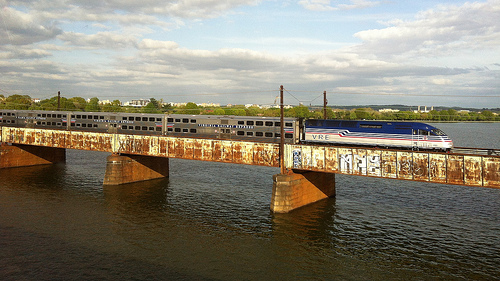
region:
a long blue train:
[303, 116, 455, 145]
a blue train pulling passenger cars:
[0, 106, 451, 148]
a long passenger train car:
[164, 115, 295, 142]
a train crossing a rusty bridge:
[0, 102, 495, 184]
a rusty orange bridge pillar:
[273, 160, 349, 209]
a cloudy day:
[364, 0, 497, 62]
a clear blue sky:
[219, 7, 374, 52]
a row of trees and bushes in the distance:
[3, 95, 496, 120]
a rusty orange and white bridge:
[0, 127, 492, 213]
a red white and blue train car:
[301, 120, 454, 143]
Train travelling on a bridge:
[4, 31, 456, 238]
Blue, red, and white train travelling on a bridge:
[17, 84, 464, 219]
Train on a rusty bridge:
[125, 95, 497, 229]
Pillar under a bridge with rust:
[263, 168, 342, 225]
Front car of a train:
[292, 117, 455, 154]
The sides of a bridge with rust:
[117, 136, 299, 167]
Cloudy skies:
[66, 20, 455, 80]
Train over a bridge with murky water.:
[2, 103, 499, 230]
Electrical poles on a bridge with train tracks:
[269, 80, 334, 230]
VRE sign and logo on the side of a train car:
[309, 124, 356, 150]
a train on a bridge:
[44, 29, 361, 254]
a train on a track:
[43, 51, 499, 272]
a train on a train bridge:
[76, 43, 481, 278]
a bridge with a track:
[136, 54, 458, 272]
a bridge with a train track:
[89, 62, 486, 261]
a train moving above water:
[93, 63, 399, 271]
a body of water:
[87, 184, 355, 276]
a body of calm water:
[85, 173, 365, 278]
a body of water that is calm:
[89, 177, 233, 265]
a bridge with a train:
[124, 72, 479, 252]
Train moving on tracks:
[0, 103, 499, 158]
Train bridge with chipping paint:
[0, 124, 499, 212]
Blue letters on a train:
[308, 131, 332, 139]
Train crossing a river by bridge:
[0, 106, 498, 215]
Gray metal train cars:
[1, 105, 298, 142]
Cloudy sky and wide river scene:
[2, 1, 497, 279]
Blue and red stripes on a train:
[280, 123, 450, 144]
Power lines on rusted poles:
[1, 84, 328, 177]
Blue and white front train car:
[299, 115, 453, 154]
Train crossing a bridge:
[0, 102, 498, 213]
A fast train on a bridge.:
[3, 103, 453, 150]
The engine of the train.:
[300, 111, 451, 146]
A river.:
[340, 191, 485, 271]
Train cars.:
[5, 106, 295, 141]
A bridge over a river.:
[2, 123, 499, 200]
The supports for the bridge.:
[265, 166, 337, 206]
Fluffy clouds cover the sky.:
[10, 11, 70, 77]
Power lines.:
[250, 76, 495, 106]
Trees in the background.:
[65, 90, 331, 115]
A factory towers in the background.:
[415, 104, 437, 114]